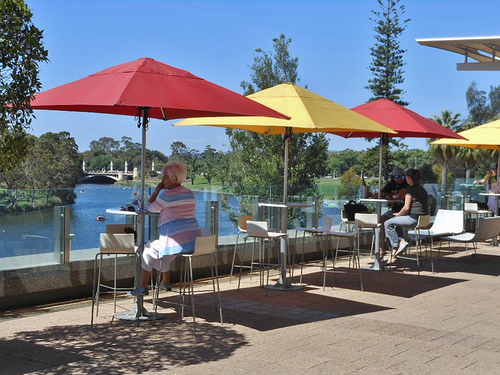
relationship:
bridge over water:
[86, 151, 173, 201] [25, 186, 102, 245]